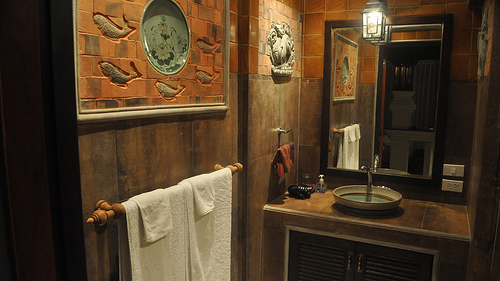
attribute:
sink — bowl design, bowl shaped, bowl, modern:
[328, 167, 403, 220]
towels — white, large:
[118, 166, 237, 280]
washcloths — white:
[125, 169, 223, 240]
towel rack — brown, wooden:
[82, 160, 250, 234]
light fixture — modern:
[359, 4, 390, 45]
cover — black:
[355, 0, 390, 44]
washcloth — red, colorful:
[272, 141, 300, 182]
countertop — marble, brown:
[257, 183, 477, 240]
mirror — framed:
[320, 18, 442, 192]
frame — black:
[317, 13, 455, 196]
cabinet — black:
[276, 222, 442, 280]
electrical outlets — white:
[441, 181, 464, 193]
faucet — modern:
[359, 165, 377, 206]